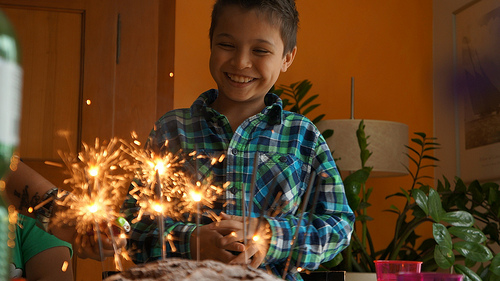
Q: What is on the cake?
A: Sparklers.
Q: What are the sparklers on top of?
A: A cake.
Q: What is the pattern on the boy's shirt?
A: Plaid.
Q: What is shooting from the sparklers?
A: Sparks.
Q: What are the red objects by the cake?
A: Plastic cups.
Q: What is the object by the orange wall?
A: A lamp.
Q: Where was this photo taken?
A: In a house.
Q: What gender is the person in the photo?
A: Male.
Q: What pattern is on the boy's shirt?
A: Plaid.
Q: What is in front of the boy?
A: A cake.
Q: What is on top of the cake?
A: Sparklers.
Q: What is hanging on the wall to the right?
A: A painting.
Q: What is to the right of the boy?
A: Plants.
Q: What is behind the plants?
A: A lamp.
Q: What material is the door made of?
A: Wood.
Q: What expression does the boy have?
A: Smiling.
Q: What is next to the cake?
A: Pink cups.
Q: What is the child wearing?
A: A plaid shirt.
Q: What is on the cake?
A: Sparklers.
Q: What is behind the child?
A: Plants.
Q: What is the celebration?
A: Party.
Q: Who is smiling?
A: Boy.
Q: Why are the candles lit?
A: It is his birthday.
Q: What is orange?
A: The wall.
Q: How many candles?
A: Three.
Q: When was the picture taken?
A: Evening.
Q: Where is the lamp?
A: Behind the boy to the right.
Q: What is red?
A: Glasses on the table.